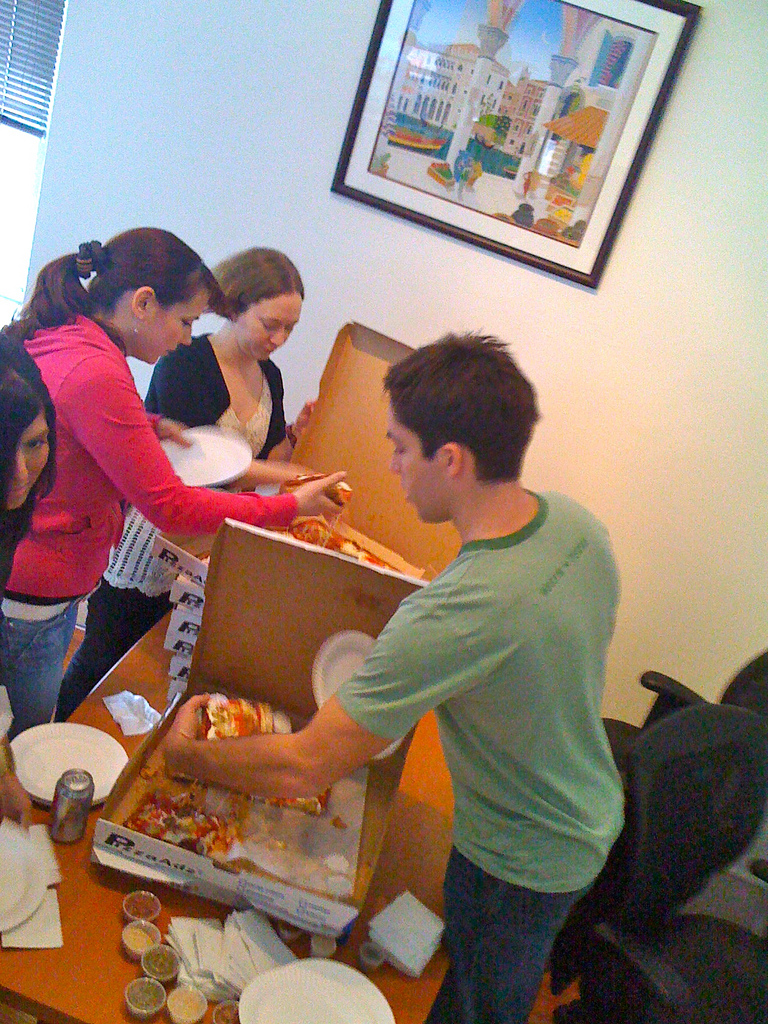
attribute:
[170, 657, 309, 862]
pizza — piece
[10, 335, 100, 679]
woman — long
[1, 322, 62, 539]
hair — brown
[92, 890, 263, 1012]
containers — plastic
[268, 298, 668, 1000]
guy — brown haired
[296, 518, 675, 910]
shirt — green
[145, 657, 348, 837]
pizza — piece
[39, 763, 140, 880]
soda — unopened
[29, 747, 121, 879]
can — silver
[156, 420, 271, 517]
plate — round, white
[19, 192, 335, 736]
girl — pink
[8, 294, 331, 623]
sweatshirt — pink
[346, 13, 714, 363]
picture — black framed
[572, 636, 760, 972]
chair — desk, black, bigger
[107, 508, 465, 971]
box — pizza, cardboard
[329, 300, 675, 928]
boy — green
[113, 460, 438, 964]
box — pizza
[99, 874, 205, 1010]
container — clear, top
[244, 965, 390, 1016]
paper plates — stacked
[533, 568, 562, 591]
letter — black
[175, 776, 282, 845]
pieces — few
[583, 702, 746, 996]
office chair — black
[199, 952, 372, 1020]
paper plates — stack, unused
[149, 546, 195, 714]
pizza boxes — a whole stack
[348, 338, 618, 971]
man — young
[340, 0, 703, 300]
artwork — framed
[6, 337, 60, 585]
hair — long, dark 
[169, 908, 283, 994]
napkin — white 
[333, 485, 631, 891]
shirt — green 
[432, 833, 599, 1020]
pant — jean  , dark 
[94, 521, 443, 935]
box — white 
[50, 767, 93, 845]
can — silver 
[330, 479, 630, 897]
t-shirt — green 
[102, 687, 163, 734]
napkin — Crumpled 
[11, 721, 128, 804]
plate — White 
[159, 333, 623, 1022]
man — young 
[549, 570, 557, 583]
letter — black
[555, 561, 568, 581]
letter — black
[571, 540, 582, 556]
letter — black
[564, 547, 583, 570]
letter — black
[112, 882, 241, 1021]
dishes — round